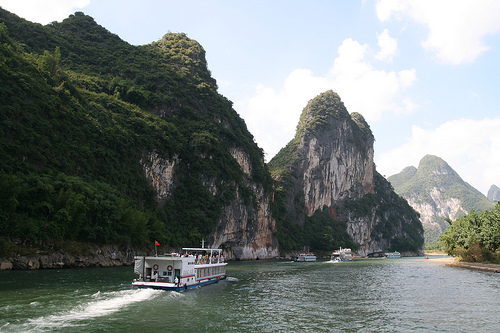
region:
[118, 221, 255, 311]
a tour boat on a river passing some rock formations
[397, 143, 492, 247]
a tall rocky hill in the distance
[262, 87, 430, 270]
a tall hill with a very rocky cliff on the side of it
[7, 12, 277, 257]
a tall hill with a steep embankment covered in foliage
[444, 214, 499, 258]
large green leafy trees on an island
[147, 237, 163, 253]
a small red flag on the back of the boat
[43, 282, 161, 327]
water churned up to a white color from the boat's motor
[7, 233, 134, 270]
a very rocky shoreline of the river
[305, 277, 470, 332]
rather calm greenish water of the river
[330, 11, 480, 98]
a blue sky with puffy white clouds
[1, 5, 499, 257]
THE MOUNTAINS ARE HIGH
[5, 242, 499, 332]
THE WATER IS CALM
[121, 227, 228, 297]
THE BOAT IS WHITE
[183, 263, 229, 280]
THE BOAT HAS MANY WINDOWS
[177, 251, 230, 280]
THE BOAT HAS MANY PEOPLE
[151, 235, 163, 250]
THE WINDSOCK IS RED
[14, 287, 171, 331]
THE BOAT IS CHURNING THE WATER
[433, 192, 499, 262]
THE TREES ARE LUSH AND GREEN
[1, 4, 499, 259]
THE GREENERY ON THE MOUNTAIN IS LUSH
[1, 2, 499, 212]
THE CLOUDY SKY IS BRIGHT AND BLUE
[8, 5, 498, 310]
a beautiful photo of mountains in the water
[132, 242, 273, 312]
a sightseeing boat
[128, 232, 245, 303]
many people are on the boat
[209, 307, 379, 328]
the water is green in color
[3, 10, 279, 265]
the mountain is covered in trees & other greenery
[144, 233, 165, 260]
a red flag on the boat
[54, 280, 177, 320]
the wake of the boat is white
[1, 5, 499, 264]
many mountains line the waterway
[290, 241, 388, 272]
other boats are in the background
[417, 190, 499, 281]
an island with trees on the right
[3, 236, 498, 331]
green colored river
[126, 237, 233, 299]
white colored party boat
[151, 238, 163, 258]
red flag on a white boat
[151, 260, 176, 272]
two life rings on the back of the white boat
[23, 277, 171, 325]
white waves caused by the boat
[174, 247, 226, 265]
people standing on the top deck of a boat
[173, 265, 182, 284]
right back door on a boat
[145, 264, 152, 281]
left back door on a boat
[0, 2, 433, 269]
rocky hill covered in greenery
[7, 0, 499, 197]
blue sky with clouds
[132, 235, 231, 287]
the boat on the water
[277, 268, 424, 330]
the body of water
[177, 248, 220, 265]
the people on the top of the boat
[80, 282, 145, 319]
the white water behind the boat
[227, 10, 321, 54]
the clear blue sky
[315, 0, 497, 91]
the clouds in the sky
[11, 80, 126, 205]
the trees on the mountain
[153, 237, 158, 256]
the flag on the boat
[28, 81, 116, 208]
the trees on the mountain closest to the boat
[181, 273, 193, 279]
the red line on the boat